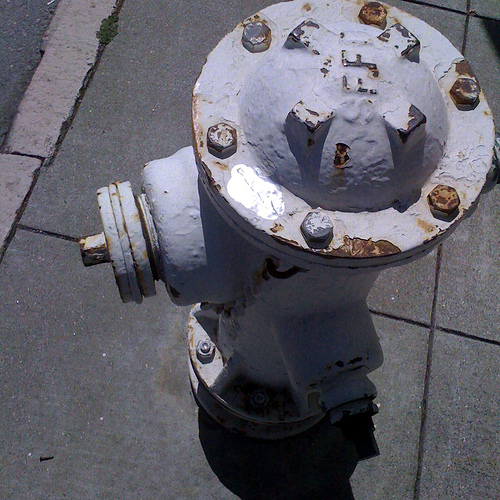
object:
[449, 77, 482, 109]
bolt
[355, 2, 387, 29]
bolt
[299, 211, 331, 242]
bolt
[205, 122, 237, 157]
bolt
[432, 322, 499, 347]
lines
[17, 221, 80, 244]
lines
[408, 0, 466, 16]
lines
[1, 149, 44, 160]
lines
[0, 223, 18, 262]
lines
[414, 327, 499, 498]
cement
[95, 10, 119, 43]
weeds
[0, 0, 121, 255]
curb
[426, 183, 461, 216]
bolt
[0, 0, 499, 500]
sidewalk